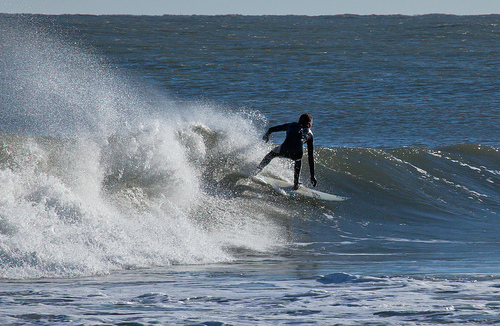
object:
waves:
[4, 271, 442, 321]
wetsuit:
[249, 122, 317, 191]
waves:
[0, 112, 499, 280]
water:
[0, 146, 255, 275]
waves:
[269, 137, 500, 244]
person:
[249, 114, 318, 191]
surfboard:
[242, 172, 351, 202]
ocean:
[0, 16, 498, 325]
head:
[298, 112, 314, 130]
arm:
[305, 136, 316, 177]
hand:
[308, 177, 321, 187]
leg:
[291, 159, 302, 185]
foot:
[292, 182, 300, 190]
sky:
[0, 0, 498, 15]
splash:
[1, 21, 162, 135]